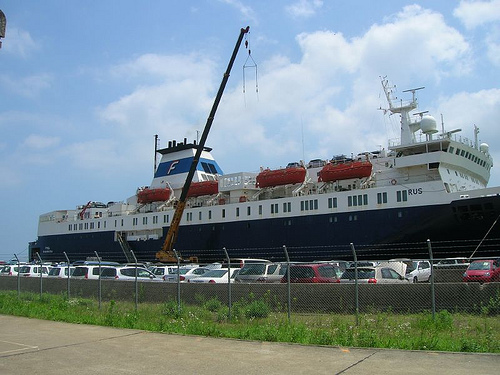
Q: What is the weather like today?
A: It is cloudy.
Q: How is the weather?
A: It is cloudy.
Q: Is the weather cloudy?
A: Yes, it is cloudy.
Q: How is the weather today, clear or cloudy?
A: It is cloudy.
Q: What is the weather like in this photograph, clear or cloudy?
A: It is cloudy.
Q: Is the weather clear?
A: No, it is cloudy.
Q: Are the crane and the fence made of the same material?
A: Yes, both the crane and the fence are made of metal.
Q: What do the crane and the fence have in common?
A: The material, both the crane and the fence are metallic.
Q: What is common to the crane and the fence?
A: The material, both the crane and the fence are metallic.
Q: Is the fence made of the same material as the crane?
A: Yes, both the fence and the crane are made of metal.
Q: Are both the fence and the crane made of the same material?
A: Yes, both the fence and the crane are made of metal.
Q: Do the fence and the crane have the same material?
A: Yes, both the fence and the crane are made of metal.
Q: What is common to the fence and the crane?
A: The material, both the fence and the crane are metallic.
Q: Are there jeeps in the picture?
A: No, there are no jeeps.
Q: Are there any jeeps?
A: No, there are no jeeps.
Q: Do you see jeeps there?
A: No, there are no jeeps.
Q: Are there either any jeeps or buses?
A: No, there are no jeeps or buses.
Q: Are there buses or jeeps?
A: No, there are no jeeps or buses.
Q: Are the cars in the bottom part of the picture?
A: Yes, the cars are in the bottom of the image.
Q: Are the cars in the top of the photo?
A: No, the cars are in the bottom of the image.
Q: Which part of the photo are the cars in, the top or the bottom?
A: The cars are in the bottom of the image.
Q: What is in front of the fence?
A: The cars are in front of the fence.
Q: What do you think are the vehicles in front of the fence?
A: The vehicles are cars.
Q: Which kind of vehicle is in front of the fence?
A: The vehicles are cars.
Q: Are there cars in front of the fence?
A: Yes, there are cars in front of the fence.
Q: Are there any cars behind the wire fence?
A: No, the cars are in front of the fence.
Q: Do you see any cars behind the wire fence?
A: No, the cars are in front of the fence.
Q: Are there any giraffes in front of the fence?
A: No, there are cars in front of the fence.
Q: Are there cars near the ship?
A: Yes, there are cars near the ship.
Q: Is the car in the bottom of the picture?
A: Yes, the car is in the bottom of the image.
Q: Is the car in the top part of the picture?
A: No, the car is in the bottom of the image.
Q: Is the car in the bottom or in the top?
A: The car is in the bottom of the image.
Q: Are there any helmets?
A: No, there are no helmets.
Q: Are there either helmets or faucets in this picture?
A: No, there are no helmets or faucets.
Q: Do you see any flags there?
A: No, there are no flags.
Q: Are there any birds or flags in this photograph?
A: No, there are no flags or birds.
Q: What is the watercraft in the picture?
A: The watercraft is a ship.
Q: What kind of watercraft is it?
A: The watercraft is a ship.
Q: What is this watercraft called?
A: This is a ship.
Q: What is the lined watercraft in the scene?
A: The watercraft is a ship.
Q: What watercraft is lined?
A: The watercraft is a ship.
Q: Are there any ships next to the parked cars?
A: Yes, there is a ship next to the cars.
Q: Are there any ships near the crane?
A: Yes, there is a ship near the crane.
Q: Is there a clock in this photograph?
A: No, there are no clocks.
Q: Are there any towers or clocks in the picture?
A: No, there are no clocks or towers.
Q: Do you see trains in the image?
A: No, there are no trains.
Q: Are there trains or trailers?
A: No, there are no trains or trailers.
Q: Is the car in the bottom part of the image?
A: Yes, the car is in the bottom of the image.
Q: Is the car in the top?
A: No, the car is in the bottom of the image.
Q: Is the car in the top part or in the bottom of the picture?
A: The car is in the bottom of the image.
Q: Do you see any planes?
A: No, there are no planes.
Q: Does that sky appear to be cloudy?
A: Yes, the sky is cloudy.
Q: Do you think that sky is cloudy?
A: Yes, the sky is cloudy.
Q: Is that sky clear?
A: No, the sky is cloudy.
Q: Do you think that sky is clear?
A: No, the sky is cloudy.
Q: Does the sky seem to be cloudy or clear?
A: The sky is cloudy.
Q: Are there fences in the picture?
A: Yes, there is a fence.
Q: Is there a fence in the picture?
A: Yes, there is a fence.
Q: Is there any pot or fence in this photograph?
A: Yes, there is a fence.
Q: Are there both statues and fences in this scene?
A: No, there is a fence but no statues.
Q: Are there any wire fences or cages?
A: Yes, there is a wire fence.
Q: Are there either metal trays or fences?
A: Yes, there is a metal fence.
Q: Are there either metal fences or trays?
A: Yes, there is a metal fence.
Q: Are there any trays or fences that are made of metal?
A: Yes, the fence is made of metal.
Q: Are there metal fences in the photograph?
A: Yes, there is a metal fence.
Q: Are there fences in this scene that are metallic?
A: Yes, there is a fence that is metallic.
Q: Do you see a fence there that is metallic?
A: Yes, there is a fence that is metallic.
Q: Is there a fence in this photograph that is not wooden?
A: Yes, there is a metallic fence.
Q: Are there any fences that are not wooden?
A: Yes, there is a metallic fence.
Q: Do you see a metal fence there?
A: Yes, there is a fence that is made of metal.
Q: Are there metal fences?
A: Yes, there is a fence that is made of metal.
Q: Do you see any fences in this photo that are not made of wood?
A: Yes, there is a fence that is made of metal.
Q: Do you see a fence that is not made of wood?
A: Yes, there is a fence that is made of metal.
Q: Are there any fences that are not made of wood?
A: Yes, there is a fence that is made of metal.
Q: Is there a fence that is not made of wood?
A: Yes, there is a fence that is made of metal.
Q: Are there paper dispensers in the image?
A: No, there are no paper dispensers.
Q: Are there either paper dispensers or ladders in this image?
A: No, there are no paper dispensers or ladders.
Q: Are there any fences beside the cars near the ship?
A: Yes, there is a fence beside the cars.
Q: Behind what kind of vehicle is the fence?
A: The fence is behind the cars.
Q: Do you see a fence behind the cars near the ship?
A: Yes, there is a fence behind the cars.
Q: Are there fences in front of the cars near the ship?
A: No, the fence is behind the cars.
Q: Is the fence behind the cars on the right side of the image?
A: Yes, the fence is behind the cars.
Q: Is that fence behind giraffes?
A: No, the fence is behind the cars.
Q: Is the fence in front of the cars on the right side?
A: No, the fence is behind the cars.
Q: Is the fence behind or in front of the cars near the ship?
A: The fence is behind the cars.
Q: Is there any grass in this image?
A: Yes, there is grass.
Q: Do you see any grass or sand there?
A: Yes, there is grass.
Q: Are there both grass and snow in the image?
A: No, there is grass but no snow.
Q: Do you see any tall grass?
A: Yes, there is tall grass.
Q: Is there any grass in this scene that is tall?
A: Yes, there is grass that is tall.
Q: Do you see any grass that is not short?
A: Yes, there is tall grass.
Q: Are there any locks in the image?
A: No, there are no locks.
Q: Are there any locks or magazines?
A: No, there are no locks or magazines.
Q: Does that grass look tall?
A: Yes, the grass is tall.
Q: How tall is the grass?
A: The grass is tall.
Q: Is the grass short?
A: No, the grass is tall.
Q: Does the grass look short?
A: No, the grass is tall.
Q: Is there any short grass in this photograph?
A: No, there is grass but it is tall.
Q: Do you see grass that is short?
A: No, there is grass but it is tall.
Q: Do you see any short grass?
A: No, there is grass but it is tall.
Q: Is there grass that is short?
A: No, there is grass but it is tall.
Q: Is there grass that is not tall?
A: No, there is grass but it is tall.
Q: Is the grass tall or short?
A: The grass is tall.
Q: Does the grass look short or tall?
A: The grass is tall.